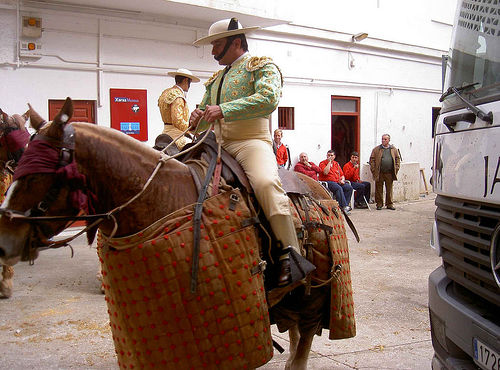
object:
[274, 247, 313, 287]
foot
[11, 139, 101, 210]
blindfold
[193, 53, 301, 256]
outfit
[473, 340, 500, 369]
license plate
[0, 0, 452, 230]
building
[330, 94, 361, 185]
door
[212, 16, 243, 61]
black strap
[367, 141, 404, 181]
brown coat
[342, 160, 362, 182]
red shirt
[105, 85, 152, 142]
red sign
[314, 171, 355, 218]
chair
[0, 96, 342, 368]
horse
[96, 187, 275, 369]
cloth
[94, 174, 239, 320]
chest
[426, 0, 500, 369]
truck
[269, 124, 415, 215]
row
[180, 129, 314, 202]
saddle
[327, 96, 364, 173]
doorway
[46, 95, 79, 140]
ear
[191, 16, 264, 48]
hat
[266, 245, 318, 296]
stirrup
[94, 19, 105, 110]
pipe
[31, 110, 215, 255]
rope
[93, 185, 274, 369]
blanket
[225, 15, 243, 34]
trim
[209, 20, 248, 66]
head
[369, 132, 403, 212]
man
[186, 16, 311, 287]
man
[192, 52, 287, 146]
jacket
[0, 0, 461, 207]
wall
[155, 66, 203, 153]
man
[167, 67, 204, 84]
hat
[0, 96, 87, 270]
head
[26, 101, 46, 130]
ear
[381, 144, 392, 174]
shirt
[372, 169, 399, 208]
pants